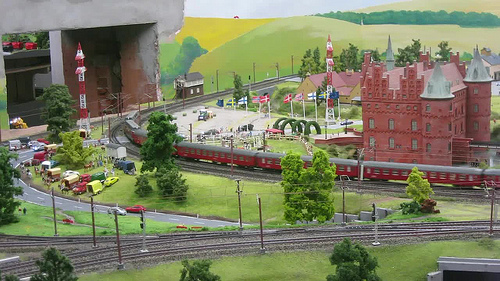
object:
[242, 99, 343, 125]
posts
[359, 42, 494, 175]
building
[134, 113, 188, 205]
trees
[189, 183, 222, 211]
grass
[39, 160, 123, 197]
vehicles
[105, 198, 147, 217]
cars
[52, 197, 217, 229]
road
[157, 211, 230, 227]
street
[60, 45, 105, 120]
tower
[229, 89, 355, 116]
flags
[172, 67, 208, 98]
house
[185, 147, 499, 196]
train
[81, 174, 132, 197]
car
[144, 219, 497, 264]
railroads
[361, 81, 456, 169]
station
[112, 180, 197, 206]
hill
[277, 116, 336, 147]
hedges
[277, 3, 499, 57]
background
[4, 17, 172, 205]
left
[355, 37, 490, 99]
towers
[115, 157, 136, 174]
wagon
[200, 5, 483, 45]
mountains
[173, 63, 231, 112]
booth